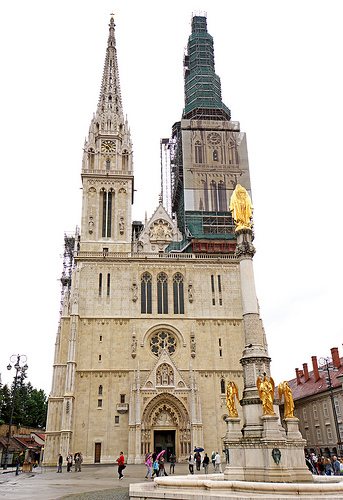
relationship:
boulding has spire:
[41, 12, 270, 467] [80, 11, 133, 177]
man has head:
[116, 450, 125, 478] [119, 450, 123, 454]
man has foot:
[116, 451, 126, 481] [118, 474, 123, 479]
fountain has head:
[128, 372, 343, 500] [270, 446, 286, 465]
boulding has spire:
[36, 7, 272, 468] [81, 12, 133, 174]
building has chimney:
[287, 346, 339, 452] [307, 352, 321, 381]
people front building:
[52, 444, 342, 479] [36, 10, 290, 470]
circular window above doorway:
[142, 320, 187, 362] [137, 391, 193, 463]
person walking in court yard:
[56, 451, 62, 471] [0, 462, 226, 498]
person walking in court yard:
[66, 451, 72, 470] [0, 462, 226, 498]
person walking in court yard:
[73, 451, 81, 471] [0, 462, 226, 498]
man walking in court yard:
[116, 451, 126, 481] [0, 462, 226, 498]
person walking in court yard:
[144, 451, 152, 477] [0, 462, 226, 498]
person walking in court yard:
[152, 454, 159, 476] [0, 462, 226, 498]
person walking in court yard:
[159, 457, 164, 477] [0, 462, 226, 498]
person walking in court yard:
[168, 454, 175, 475] [0, 462, 226, 498]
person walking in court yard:
[189, 452, 194, 474] [0, 462, 226, 498]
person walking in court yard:
[187, 453, 194, 474] [0, 462, 226, 498]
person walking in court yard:
[194, 451, 200, 470] [0, 462, 226, 498]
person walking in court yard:
[201, 452, 209, 473] [0, 462, 226, 498]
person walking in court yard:
[212, 451, 222, 473] [0, 462, 226, 498]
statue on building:
[227, 181, 255, 233] [18, 7, 320, 497]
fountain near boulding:
[125, 378, 342, 495] [41, 12, 270, 467]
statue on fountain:
[257, 374, 278, 416] [121, 181, 340, 499]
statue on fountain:
[225, 378, 239, 417] [121, 181, 340, 499]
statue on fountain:
[278, 381, 297, 418] [121, 181, 340, 499]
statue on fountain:
[228, 183, 253, 233] [121, 181, 340, 499]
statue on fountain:
[252, 372, 278, 416] [121, 181, 340, 499]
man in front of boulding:
[116, 451, 126, 481] [41, 12, 270, 467]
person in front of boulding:
[168, 450, 176, 475] [41, 12, 270, 467]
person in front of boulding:
[189, 452, 194, 474] [41, 12, 270, 467]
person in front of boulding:
[211, 451, 224, 469] [41, 12, 270, 467]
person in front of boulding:
[195, 451, 200, 470] [41, 12, 270, 467]